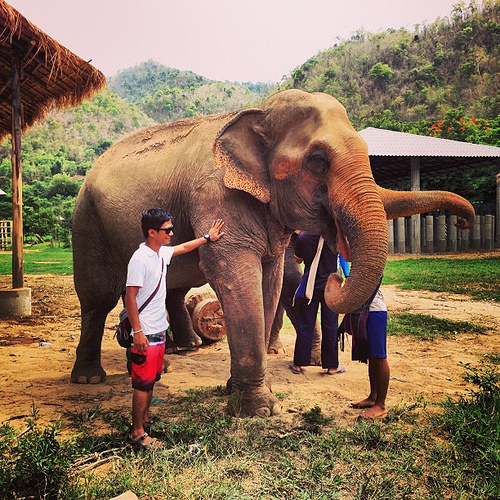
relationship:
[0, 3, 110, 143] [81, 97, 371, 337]
roof near elephant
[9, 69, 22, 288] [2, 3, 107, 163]
pole supporting roof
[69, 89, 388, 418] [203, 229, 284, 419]
elephant leading with foot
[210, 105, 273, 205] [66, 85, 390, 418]
ear of elephant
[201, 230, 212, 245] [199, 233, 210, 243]
watch on wrist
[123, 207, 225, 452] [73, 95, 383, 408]
man touching elephant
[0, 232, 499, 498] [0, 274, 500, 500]
grass in dirt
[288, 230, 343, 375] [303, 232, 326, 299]
person wearing stripe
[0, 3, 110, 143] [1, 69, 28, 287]
roof supported by pole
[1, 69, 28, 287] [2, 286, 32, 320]
pole in cement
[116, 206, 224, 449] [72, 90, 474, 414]
man touching elephant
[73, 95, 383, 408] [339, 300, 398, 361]
elephant wearing shorts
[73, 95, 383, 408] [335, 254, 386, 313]
elephant wearing shirt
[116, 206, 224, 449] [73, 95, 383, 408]
man touching t elephant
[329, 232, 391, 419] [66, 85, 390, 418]
person behind elephant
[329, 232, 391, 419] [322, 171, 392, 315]
person behind trunk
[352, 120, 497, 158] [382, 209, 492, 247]
roof over pole fencing